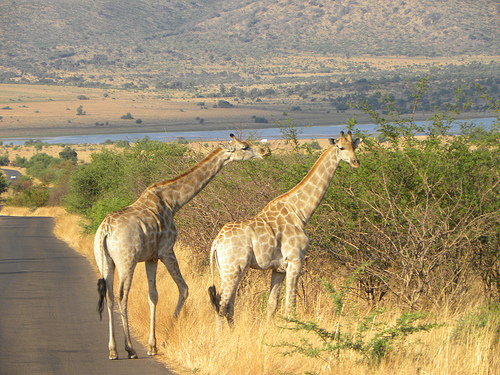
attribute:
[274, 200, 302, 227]
spots — brown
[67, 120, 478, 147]
water — blue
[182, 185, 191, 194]
spot — brown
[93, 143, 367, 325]
giraffes — male and female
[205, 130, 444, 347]
giraffe — avoiding traffic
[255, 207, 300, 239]
spots — brown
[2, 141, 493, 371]
bushes — green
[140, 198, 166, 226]
spots — brown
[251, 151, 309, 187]
tree top — green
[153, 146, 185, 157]
tree top — green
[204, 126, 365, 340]
giraffe — standing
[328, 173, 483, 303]
stems — brown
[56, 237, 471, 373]
grass — dry